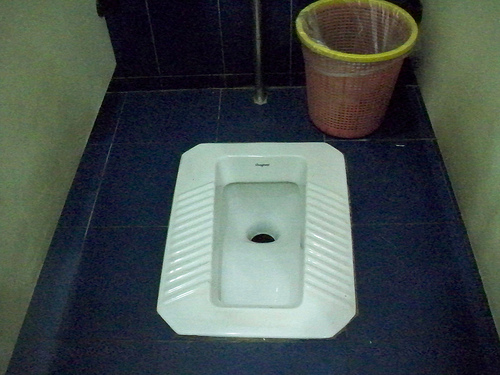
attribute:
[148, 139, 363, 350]
toilet — white, clean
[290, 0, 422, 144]
dust bin — yellow, red, clean, brown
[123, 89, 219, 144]
tile — black, blue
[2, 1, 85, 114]
wall — green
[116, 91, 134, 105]
line — white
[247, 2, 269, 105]
pipe — dark, silver